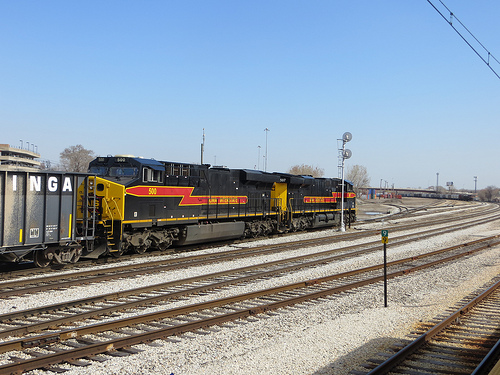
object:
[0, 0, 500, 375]
photo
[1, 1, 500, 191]
sky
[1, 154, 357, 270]
train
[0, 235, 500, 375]
tracks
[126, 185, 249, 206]
stripe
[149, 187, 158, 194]
numbers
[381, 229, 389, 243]
sign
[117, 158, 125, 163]
lights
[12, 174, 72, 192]
letters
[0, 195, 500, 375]
ground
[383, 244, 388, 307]
pole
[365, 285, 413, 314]
rocks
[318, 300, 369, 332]
gravel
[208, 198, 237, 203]
letters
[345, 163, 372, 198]
tree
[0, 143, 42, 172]
building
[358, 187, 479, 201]
layers